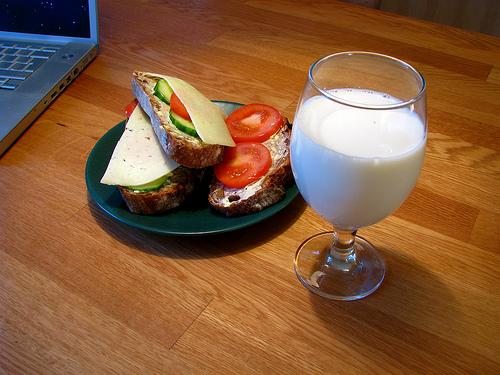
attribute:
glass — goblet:
[287, 48, 429, 304]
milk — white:
[289, 86, 427, 230]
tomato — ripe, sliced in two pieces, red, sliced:
[213, 101, 285, 191]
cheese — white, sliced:
[144, 67, 237, 150]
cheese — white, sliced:
[97, 98, 183, 188]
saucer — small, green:
[83, 99, 301, 240]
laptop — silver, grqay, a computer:
[0, 1, 103, 161]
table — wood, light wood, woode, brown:
[0, 1, 498, 373]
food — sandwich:
[99, 69, 297, 221]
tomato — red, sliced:
[166, 89, 192, 124]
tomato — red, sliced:
[122, 100, 137, 119]